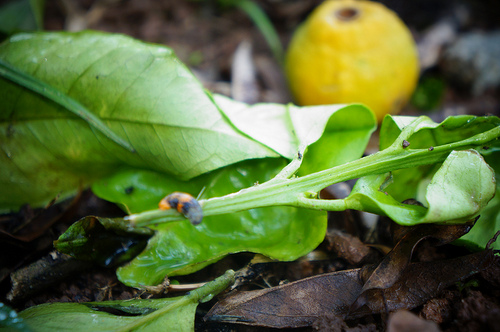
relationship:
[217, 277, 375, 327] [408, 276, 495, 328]
dead leaf on ground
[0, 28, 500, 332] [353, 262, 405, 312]
leaves on ground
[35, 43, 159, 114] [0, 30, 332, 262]
veins of leaf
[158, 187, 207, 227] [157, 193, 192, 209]
insect with stripes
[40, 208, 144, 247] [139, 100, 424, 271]
stem broken from plant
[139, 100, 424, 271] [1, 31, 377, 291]
plant with leaf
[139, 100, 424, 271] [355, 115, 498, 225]
plant with leaf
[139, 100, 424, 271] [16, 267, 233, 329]
plant with leaf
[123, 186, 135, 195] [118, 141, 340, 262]
bug on leaf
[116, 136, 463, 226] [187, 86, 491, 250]
stem on leaf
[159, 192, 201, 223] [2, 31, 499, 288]
bug on plant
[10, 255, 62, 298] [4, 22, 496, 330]
stem on plant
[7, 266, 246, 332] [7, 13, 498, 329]
leaf on ground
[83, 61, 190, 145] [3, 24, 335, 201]
veins on leaf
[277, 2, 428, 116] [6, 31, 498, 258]
lemon on leaves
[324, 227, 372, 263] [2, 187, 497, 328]
bark on ground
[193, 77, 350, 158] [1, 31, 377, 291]
reflection on leaf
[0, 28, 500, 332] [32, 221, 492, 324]
leaves on ground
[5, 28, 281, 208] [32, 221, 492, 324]
leaves on ground